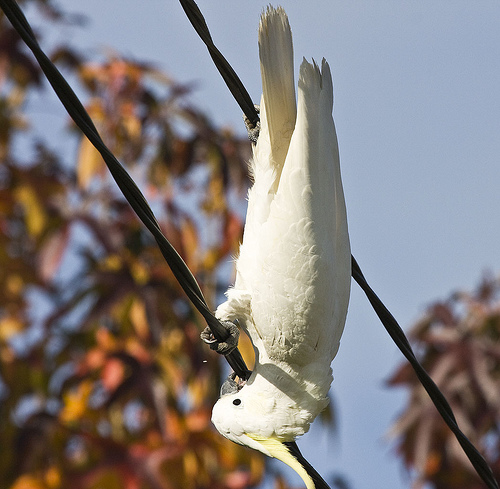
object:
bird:
[195, 6, 352, 486]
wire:
[7, 0, 212, 294]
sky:
[0, 2, 500, 487]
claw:
[199, 315, 243, 355]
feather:
[251, 433, 322, 489]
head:
[211, 375, 316, 489]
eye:
[232, 399, 241, 406]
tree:
[5, 81, 242, 485]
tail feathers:
[256, 10, 299, 143]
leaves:
[7, 372, 112, 484]